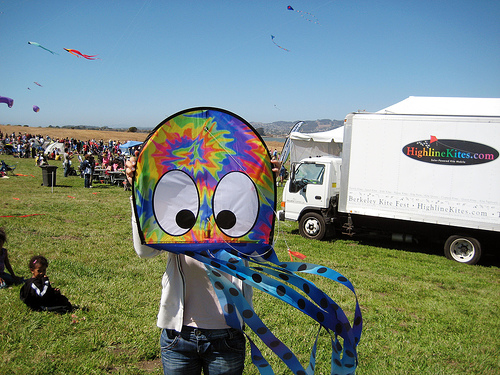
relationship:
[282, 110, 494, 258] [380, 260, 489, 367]
truck parked on grass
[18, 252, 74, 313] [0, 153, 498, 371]
girl on grass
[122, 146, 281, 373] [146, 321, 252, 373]
person wearing jeans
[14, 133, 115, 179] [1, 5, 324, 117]
crowd watching kites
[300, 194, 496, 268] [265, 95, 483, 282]
tires on truck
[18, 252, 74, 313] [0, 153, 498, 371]
girl sits in grass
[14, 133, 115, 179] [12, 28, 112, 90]
crowd of people are watching kites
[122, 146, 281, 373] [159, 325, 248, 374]
person wearing jeans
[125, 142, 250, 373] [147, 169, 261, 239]
woman holding up a kite with big eyes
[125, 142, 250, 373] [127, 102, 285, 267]
woman holding up a kite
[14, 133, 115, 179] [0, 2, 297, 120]
crowd gathered together watching kites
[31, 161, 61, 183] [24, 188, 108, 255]
trash can sitting on grass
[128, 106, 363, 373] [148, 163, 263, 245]
kite with eyeballs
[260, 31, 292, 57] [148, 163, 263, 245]
kite with eyeballs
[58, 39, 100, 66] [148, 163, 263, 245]
kite with eyeballs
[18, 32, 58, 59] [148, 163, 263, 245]
kite with eyeballs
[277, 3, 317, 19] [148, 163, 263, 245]
kite with eyeballs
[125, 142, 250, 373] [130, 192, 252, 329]
woman wearing white shirt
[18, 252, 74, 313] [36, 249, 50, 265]
girl with bow in hair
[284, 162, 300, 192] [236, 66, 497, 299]
mirror on a box truck